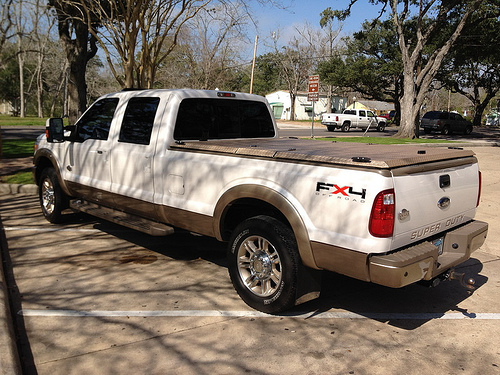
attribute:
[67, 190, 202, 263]
board — stepping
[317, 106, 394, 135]
truck — white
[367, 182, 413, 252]
light — red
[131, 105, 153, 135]
tints — black